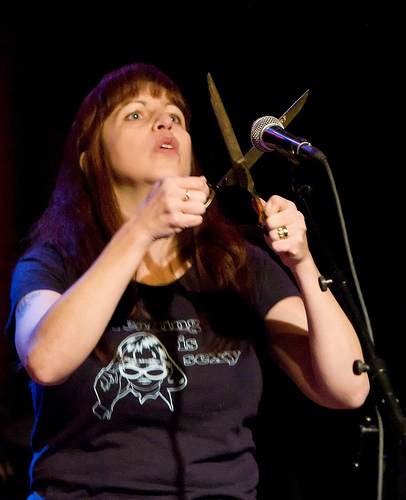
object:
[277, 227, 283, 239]
ring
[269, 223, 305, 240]
finger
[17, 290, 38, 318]
tatto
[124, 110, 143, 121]
eye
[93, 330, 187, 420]
girl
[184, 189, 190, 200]
ring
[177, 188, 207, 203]
finger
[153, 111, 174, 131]
nose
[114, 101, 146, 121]
eyebrows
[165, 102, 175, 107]
eyebrows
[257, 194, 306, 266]
hand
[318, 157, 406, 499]
stand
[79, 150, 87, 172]
ear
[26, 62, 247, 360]
hair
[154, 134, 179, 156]
lips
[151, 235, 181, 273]
light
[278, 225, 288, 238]
rings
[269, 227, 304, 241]
ring finger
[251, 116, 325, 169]
microphone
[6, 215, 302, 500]
shirt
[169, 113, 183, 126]
eye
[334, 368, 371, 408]
elbow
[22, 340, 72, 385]
elbow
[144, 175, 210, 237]
hand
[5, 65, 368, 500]
girl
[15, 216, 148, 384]
arm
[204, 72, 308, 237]
scissors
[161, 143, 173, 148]
teeth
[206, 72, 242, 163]
blades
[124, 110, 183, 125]
eyes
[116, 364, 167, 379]
glasses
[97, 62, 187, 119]
bangs